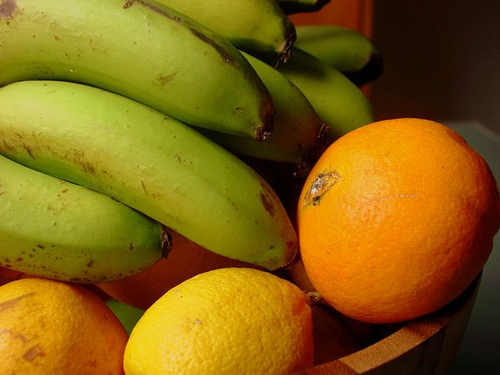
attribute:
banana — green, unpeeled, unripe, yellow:
[0, 0, 278, 143]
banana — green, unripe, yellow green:
[0, 79, 301, 270]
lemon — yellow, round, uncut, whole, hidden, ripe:
[122, 268, 314, 374]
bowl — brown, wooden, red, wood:
[296, 243, 493, 374]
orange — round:
[298, 118, 499, 324]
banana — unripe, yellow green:
[0, 157, 171, 283]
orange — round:
[1, 274, 130, 374]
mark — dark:
[0, 290, 31, 327]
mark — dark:
[26, 343, 47, 364]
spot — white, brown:
[311, 175, 324, 196]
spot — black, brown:
[311, 193, 322, 207]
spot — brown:
[24, 142, 36, 161]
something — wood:
[281, 0, 373, 105]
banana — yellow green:
[202, 39, 328, 166]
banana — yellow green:
[252, 40, 373, 137]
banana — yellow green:
[288, 23, 383, 86]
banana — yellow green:
[158, 0, 298, 61]